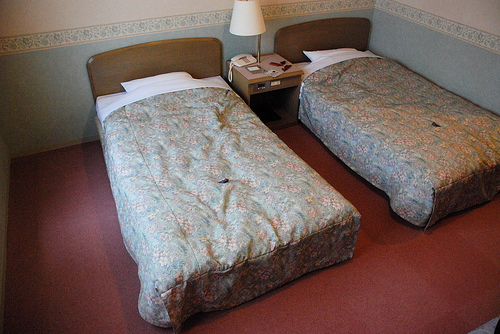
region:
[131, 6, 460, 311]
two beds in a room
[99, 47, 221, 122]
pillows on a bed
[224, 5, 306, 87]
a light near a bed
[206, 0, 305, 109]
a phone on a night stand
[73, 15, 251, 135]
a head board on a bed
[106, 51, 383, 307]
a blanket on a bed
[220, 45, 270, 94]
a phone near a bed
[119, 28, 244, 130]
a white pillow on a bed in a room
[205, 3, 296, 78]
the lampshade near a bed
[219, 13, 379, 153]
a nightstand between two beds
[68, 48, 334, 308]
a twin size bed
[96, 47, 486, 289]
two twin size beds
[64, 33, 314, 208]
a wooden headboard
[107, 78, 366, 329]
a flowered bedspread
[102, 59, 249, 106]
a white pillow on a bed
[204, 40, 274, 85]
a white phone with a cord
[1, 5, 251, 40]
flowered wall paper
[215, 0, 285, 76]
a white bedside lamp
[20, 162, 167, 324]
maroon carpet in a bedroom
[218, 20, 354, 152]
a table between two beds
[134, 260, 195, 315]
PArt of floral bed spread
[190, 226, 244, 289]
PArt of floral bed spread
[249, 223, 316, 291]
PArt of floral bed spread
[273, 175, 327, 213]
PArt of floral bed spread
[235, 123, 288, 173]
PArt of floral bed spread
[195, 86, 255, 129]
PArt of floral bed spread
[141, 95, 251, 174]
PArt of floral bed spread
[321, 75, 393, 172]
PArt of floral bed spread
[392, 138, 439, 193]
PArt of floral bed spread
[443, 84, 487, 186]
PArt of floral bed spread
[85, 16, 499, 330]
two beds on bedroom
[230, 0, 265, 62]
white bedside lamp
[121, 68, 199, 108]
white pillow in bed in left side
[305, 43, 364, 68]
white pillow in bed in right side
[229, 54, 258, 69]
white phone above nightstand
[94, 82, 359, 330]
flowery blue and pink sheets in bed in left side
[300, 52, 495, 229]
flowery blue and pink sheets in bed in right side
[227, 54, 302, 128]
light brown wooden nightstand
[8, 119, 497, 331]
floor is red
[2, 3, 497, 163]
walls are light blue and white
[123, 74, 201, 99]
white pillow on bed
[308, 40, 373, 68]
white pillow on bed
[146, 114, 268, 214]
floral cover on bed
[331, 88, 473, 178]
floral cover on bed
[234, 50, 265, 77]
white phone on table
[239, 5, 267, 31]
white shade on lamp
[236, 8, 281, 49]
tall lamp on table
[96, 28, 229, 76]
wood board on bad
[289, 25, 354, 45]
wood board on bed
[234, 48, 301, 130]
small table by bed